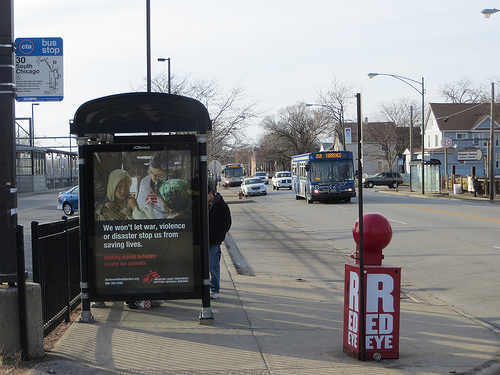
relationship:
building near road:
[402, 101, 498, 189] [229, 175, 499, 333]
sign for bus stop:
[15, 37, 63, 102] [70, 91, 219, 326]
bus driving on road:
[290, 150, 357, 204] [238, 176, 498, 323]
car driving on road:
[271, 171, 292, 191] [255, 189, 498, 328]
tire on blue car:
[64, 202, 74, 217] [56, 185, 78, 215]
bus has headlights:
[290, 150, 357, 204] [309, 186, 354, 196]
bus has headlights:
[277, 138, 389, 233] [301, 188, 375, 200]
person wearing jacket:
[201, 173, 243, 313] [204, 189, 242, 245]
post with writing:
[343, 212, 401, 362] [345, 269, 395, 351]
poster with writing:
[92, 149, 194, 295] [98, 222, 194, 291]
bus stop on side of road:
[413, 152, 442, 199] [217, 149, 484, 359]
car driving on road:
[239, 178, 268, 199] [217, 175, 498, 367]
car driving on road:
[271, 168, 288, 190] [217, 175, 498, 367]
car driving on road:
[252, 170, 268, 184] [217, 175, 498, 367]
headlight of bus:
[306, 180, 324, 201] [297, 147, 362, 201]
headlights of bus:
[347, 188, 352, 192] [290, 149, 357, 204]